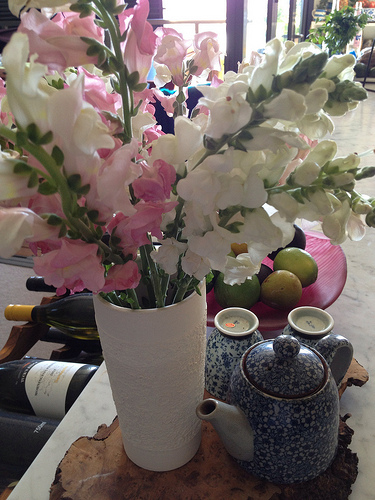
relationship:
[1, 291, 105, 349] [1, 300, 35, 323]
bottle with cap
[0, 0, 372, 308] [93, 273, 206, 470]
flowers in vase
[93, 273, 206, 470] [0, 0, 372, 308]
vase with flowers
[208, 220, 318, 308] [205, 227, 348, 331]
fruit on dish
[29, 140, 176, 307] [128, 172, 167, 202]
flowers with petals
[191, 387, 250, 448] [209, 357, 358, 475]
spout on tea pot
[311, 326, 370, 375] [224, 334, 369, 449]
handle on tea pot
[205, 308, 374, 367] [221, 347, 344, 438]
teacups by teapot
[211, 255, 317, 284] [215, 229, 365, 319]
fruit in dish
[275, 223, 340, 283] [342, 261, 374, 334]
dish on counter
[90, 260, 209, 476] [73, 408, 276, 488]
vase on slab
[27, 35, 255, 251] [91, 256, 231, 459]
flowers in vase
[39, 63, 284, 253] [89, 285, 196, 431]
flowers in vase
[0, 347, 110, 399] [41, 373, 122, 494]
bottles by table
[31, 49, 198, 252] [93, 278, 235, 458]
flowers in vase